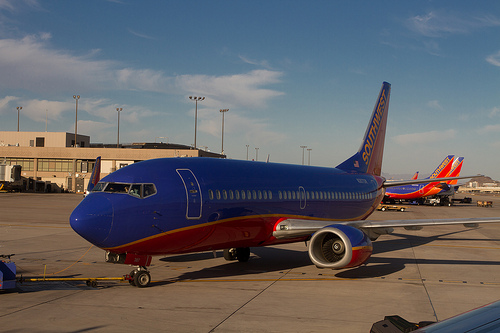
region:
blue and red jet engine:
[300, 220, 395, 280]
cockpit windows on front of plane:
[88, 178, 163, 203]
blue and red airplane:
[61, 158, 421, 288]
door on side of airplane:
[167, 166, 211, 223]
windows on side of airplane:
[202, 183, 279, 204]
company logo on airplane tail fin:
[348, 79, 395, 174]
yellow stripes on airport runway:
[174, 267, 296, 291]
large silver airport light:
[188, 90, 208, 147]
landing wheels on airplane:
[122, 268, 163, 290]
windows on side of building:
[23, 153, 76, 174]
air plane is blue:
[64, 108, 399, 313]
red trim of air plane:
[89, 198, 305, 265]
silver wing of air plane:
[235, 187, 486, 249]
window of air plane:
[85, 168, 158, 202]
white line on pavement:
[126, 253, 390, 293]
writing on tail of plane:
[350, 78, 390, 177]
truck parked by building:
[0, 153, 91, 187]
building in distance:
[5, 72, 210, 214]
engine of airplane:
[289, 217, 391, 262]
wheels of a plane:
[102, 266, 196, 300]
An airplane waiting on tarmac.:
[15, 17, 485, 318]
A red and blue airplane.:
[69, 65, 433, 299]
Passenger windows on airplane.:
[210, 184, 384, 211]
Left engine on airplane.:
[297, 222, 375, 277]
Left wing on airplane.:
[275, 202, 497, 232]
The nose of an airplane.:
[60, 160, 160, 255]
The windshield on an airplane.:
[90, 166, 160, 201]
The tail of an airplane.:
[338, 70, 398, 185]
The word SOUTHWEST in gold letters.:
[346, 77, 398, 177]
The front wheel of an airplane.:
[116, 259, 162, 295]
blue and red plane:
[72, 87, 418, 268]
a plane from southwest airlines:
[63, 116, 443, 321]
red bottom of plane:
[195, 215, 256, 250]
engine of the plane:
[307, 215, 372, 275]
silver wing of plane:
[410, 201, 488, 239]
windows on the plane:
[223, 176, 289, 211]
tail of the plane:
[330, 77, 408, 178]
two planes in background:
[413, 150, 471, 205]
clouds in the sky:
[242, 77, 297, 118]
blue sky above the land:
[304, 41, 391, 72]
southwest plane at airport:
[70, 72, 390, 265]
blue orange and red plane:
[71, 77, 396, 290]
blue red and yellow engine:
[307, 225, 380, 270]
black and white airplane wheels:
[122, 265, 150, 288]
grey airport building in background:
[0, 96, 227, 194]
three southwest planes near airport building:
[71, 80, 464, 272]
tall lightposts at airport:
[9, 94, 334, 161]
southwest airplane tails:
[346, 80, 464, 201]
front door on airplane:
[175, 165, 200, 219]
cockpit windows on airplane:
[94, 180, 157, 199]